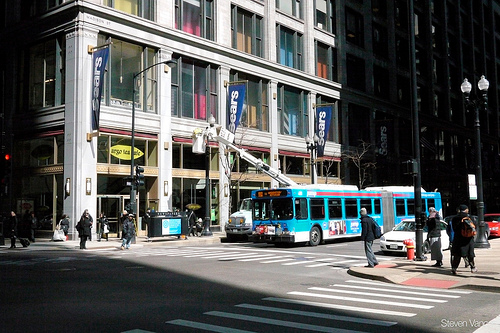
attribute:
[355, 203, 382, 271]
passenger — blue 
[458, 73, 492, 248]
street lamps — black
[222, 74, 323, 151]
banners — blue 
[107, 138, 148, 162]
sign — yellow 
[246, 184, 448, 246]
bus — blue, white 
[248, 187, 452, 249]
bus — blue 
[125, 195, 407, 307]
street — lined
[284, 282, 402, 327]
white lines — painted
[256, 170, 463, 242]
bus — blue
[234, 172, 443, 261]
bus — blue , white 